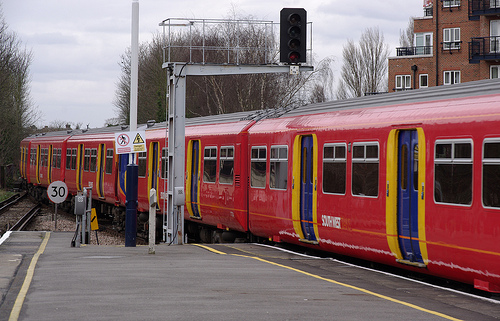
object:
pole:
[125, 152, 139, 247]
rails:
[8, 203, 44, 232]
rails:
[2, 192, 25, 209]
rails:
[158, 18, 312, 67]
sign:
[117, 133, 130, 146]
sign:
[133, 133, 145, 145]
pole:
[130, 0, 140, 132]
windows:
[249, 145, 267, 189]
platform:
[0, 223, 500, 321]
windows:
[433, 138, 474, 208]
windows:
[219, 145, 235, 184]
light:
[288, 51, 302, 63]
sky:
[50, 24, 94, 56]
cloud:
[28, 24, 57, 38]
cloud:
[81, 7, 109, 27]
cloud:
[329, 4, 368, 20]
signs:
[117, 147, 131, 154]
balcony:
[396, 45, 433, 56]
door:
[385, 127, 428, 267]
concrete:
[148, 293, 191, 317]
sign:
[47, 181, 69, 204]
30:
[51, 186, 65, 197]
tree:
[197, 74, 244, 96]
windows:
[351, 141, 380, 199]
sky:
[51, 81, 92, 93]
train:
[21, 76, 500, 293]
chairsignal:
[280, 8, 307, 63]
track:
[7, 204, 44, 232]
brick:
[451, 62, 468, 67]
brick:
[387, 60, 406, 63]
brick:
[417, 59, 432, 65]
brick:
[464, 28, 483, 34]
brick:
[470, 74, 480, 77]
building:
[387, 0, 500, 94]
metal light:
[159, 8, 315, 246]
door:
[186, 139, 202, 220]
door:
[292, 133, 321, 244]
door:
[147, 141, 160, 211]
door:
[96, 143, 107, 199]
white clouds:
[34, 17, 83, 36]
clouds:
[43, 66, 70, 87]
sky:
[367, 1, 410, 15]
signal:
[279, 8, 307, 63]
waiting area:
[0, 245, 500, 321]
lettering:
[321, 214, 341, 229]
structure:
[158, 17, 314, 246]